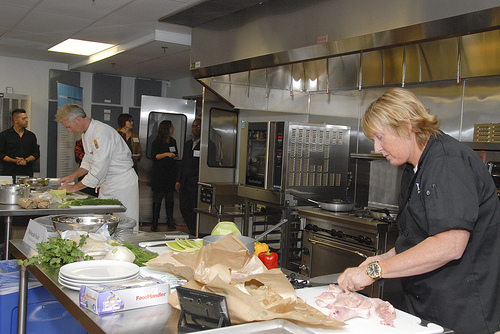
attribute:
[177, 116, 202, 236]
staff person — waiting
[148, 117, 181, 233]
staff person — waiting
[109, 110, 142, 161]
staff person — waiting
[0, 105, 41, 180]
staff person — waiting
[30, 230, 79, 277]
leaves — green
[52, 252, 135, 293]
plates — white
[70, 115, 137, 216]
outfit — white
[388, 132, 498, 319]
outfit — black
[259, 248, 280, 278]
pepper — red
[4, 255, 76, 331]
trasn can — blue